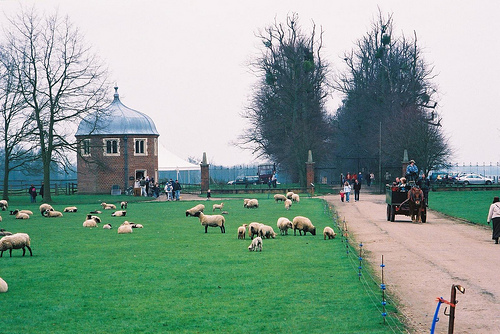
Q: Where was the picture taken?
A: It was taken at the field.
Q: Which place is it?
A: It is a field.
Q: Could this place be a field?
A: Yes, it is a field.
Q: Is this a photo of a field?
A: Yes, it is showing a field.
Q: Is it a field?
A: Yes, it is a field.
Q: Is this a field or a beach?
A: It is a field.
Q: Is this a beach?
A: No, it is a field.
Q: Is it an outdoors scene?
A: Yes, it is outdoors.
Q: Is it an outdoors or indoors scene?
A: It is outdoors.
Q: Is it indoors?
A: No, it is outdoors.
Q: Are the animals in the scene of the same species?
A: Yes, all the animals are sheep.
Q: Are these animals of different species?
A: No, all the animals are sheep.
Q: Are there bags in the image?
A: No, there are no bags.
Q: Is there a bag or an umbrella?
A: No, there are no bags or umbrellas.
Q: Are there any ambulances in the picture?
A: No, there are no ambulances.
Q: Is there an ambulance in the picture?
A: No, there are no ambulances.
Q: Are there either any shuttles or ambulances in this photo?
A: No, there are no ambulances or shuttles.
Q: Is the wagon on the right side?
A: Yes, the wagon is on the right of the image.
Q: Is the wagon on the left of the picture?
A: No, the wagon is on the right of the image.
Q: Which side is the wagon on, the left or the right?
A: The wagon is on the right of the image.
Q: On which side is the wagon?
A: The wagon is on the right of the image.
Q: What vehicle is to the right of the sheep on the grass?
A: The vehicle is a wagon.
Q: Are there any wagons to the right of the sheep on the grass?
A: Yes, there is a wagon to the right of the sheep.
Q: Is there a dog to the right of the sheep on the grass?
A: No, there is a wagon to the right of the sheep.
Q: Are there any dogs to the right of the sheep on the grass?
A: No, there is a wagon to the right of the sheep.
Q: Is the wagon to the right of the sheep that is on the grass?
A: Yes, the wagon is to the right of the sheep.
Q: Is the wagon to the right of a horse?
A: No, the wagon is to the right of the sheep.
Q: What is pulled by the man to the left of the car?
A: The wagon is pulled by the man.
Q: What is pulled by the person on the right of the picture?
A: The wagon is pulled by the man.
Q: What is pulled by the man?
A: The wagon is pulled by the man.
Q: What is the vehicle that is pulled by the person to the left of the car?
A: The vehicle is a wagon.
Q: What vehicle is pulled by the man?
A: The vehicle is a wagon.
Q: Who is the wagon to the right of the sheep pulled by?
A: The wagon is pulled by the man.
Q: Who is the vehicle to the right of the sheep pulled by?
A: The wagon is pulled by the man.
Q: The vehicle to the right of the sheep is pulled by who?
A: The wagon is pulled by the man.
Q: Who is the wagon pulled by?
A: The wagon is pulled by the man.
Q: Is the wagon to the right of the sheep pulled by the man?
A: Yes, the wagon is pulled by the man.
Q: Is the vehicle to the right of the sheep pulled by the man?
A: Yes, the wagon is pulled by the man.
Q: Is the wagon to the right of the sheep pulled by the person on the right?
A: Yes, the wagon is pulled by the man.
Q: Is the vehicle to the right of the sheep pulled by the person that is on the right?
A: Yes, the wagon is pulled by the man.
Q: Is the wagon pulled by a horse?
A: No, the wagon is pulled by the man.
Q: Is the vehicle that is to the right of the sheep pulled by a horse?
A: No, the wagon is pulled by the man.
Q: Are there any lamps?
A: No, there are no lamps.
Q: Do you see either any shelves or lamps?
A: No, there are no lamps or shelves.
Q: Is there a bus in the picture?
A: No, there are no buses.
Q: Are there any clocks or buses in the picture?
A: No, there are no buses or clocks.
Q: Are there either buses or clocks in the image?
A: No, there are no buses or clocks.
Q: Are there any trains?
A: No, there are no trains.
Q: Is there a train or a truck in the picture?
A: No, there are no trains or trucks.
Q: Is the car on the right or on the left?
A: The car is on the right of the image.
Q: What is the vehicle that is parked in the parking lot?
A: The vehicle is a car.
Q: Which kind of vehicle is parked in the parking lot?
A: The vehicle is a car.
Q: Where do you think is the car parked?
A: The car is parked in the parking lot.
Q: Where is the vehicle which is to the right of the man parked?
A: The car is parked in the parking lot.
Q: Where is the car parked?
A: The car is parked in the parking lot.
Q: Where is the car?
A: The car is on the road.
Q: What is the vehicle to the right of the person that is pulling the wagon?
A: The vehicle is a car.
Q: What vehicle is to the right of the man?
A: The vehicle is a car.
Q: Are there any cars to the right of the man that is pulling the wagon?
A: Yes, there is a car to the right of the man.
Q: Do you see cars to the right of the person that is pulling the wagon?
A: Yes, there is a car to the right of the man.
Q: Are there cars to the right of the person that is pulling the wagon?
A: Yes, there is a car to the right of the man.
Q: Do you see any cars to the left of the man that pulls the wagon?
A: No, the car is to the right of the man.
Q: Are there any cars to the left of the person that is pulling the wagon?
A: No, the car is to the right of the man.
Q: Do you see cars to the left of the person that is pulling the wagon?
A: No, the car is to the right of the man.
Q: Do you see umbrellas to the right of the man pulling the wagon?
A: No, there is a car to the right of the man.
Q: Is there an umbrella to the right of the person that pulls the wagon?
A: No, there is a car to the right of the man.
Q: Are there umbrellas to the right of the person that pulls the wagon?
A: No, there is a car to the right of the man.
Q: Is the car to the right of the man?
A: Yes, the car is to the right of the man.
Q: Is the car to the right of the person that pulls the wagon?
A: Yes, the car is to the right of the man.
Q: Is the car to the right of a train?
A: No, the car is to the right of the man.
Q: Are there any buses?
A: No, there are no buses.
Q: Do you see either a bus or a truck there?
A: No, there are no buses or trucks.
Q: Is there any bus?
A: No, there are no buses.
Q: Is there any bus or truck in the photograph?
A: No, there are no buses or trucks.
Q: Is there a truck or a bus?
A: No, there are no buses or trucks.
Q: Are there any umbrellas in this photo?
A: No, there are no umbrellas.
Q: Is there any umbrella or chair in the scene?
A: No, there are no umbrellas or chairs.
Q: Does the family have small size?
A: Yes, the family is small.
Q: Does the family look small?
A: Yes, the family is small.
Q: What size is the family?
A: The family is small.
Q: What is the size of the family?
A: The family is small.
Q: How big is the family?
A: The family is small.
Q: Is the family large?
A: No, the family is small.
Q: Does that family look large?
A: No, the family is small.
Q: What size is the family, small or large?
A: The family is small.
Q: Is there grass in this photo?
A: Yes, there is grass.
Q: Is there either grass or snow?
A: Yes, there is grass.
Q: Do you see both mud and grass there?
A: No, there is grass but no mud.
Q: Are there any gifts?
A: No, there are no gifts.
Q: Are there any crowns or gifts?
A: No, there are no gifts or crowns.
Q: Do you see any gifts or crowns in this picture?
A: No, there are no gifts or crowns.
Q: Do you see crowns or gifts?
A: No, there are no gifts or crowns.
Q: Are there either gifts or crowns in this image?
A: No, there are no gifts or crowns.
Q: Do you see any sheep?
A: Yes, there is a sheep.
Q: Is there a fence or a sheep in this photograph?
A: Yes, there is a sheep.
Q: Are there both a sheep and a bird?
A: No, there is a sheep but no birds.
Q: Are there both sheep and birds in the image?
A: No, there is a sheep but no birds.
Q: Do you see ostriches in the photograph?
A: No, there are no ostriches.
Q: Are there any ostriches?
A: No, there are no ostriches.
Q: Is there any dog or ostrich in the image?
A: No, there are no ostriches or dogs.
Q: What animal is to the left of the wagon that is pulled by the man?
A: The animal is a sheep.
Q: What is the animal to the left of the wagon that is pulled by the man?
A: The animal is a sheep.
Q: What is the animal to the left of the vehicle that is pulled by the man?
A: The animal is a sheep.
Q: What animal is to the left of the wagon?
A: The animal is a sheep.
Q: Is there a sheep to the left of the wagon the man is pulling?
A: Yes, there is a sheep to the left of the wagon.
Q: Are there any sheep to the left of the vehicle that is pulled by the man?
A: Yes, there is a sheep to the left of the wagon.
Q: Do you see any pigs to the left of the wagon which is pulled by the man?
A: No, there is a sheep to the left of the wagon.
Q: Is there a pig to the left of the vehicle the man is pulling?
A: No, there is a sheep to the left of the wagon.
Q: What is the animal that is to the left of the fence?
A: The animal is a sheep.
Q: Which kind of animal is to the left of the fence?
A: The animal is a sheep.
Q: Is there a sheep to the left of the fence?
A: Yes, there is a sheep to the left of the fence.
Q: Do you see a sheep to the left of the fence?
A: Yes, there is a sheep to the left of the fence.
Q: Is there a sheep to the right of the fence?
A: No, the sheep is to the left of the fence.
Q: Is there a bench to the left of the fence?
A: No, there is a sheep to the left of the fence.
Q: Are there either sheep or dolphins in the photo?
A: Yes, there is a sheep.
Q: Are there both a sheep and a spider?
A: No, there is a sheep but no spiders.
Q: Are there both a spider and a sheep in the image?
A: No, there is a sheep but no spiders.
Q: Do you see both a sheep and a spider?
A: No, there is a sheep but no spiders.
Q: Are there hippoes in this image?
A: No, there are no hippoes.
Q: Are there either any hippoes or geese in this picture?
A: No, there are no hippoes or geese.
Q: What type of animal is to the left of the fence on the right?
A: The animal is a sheep.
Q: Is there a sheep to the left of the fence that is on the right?
A: Yes, there is a sheep to the left of the fence.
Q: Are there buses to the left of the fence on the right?
A: No, there is a sheep to the left of the fence.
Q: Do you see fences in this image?
A: Yes, there is a fence.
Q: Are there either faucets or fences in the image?
A: Yes, there is a fence.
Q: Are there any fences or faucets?
A: Yes, there is a fence.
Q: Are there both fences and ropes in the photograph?
A: No, there is a fence but no ropes.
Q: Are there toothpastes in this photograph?
A: No, there are no toothpastes.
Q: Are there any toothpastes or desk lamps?
A: No, there are no toothpastes or desk lamps.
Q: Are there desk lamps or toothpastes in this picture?
A: No, there are no toothpastes or desk lamps.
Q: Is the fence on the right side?
A: Yes, the fence is on the right of the image.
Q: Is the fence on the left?
A: No, the fence is on the right of the image.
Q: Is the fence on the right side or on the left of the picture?
A: The fence is on the right of the image.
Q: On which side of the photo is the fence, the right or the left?
A: The fence is on the right of the image.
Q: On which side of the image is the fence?
A: The fence is on the right of the image.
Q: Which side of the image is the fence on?
A: The fence is on the right of the image.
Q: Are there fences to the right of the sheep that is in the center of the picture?
A: Yes, there is a fence to the right of the sheep.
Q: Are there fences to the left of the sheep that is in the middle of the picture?
A: No, the fence is to the right of the sheep.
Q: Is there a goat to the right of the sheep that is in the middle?
A: No, there is a fence to the right of the sheep.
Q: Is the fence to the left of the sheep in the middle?
A: No, the fence is to the right of the sheep.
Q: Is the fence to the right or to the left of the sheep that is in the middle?
A: The fence is to the right of the sheep.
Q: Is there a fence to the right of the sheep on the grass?
A: Yes, there is a fence to the right of the sheep.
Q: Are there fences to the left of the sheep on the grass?
A: No, the fence is to the right of the sheep.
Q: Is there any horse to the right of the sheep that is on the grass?
A: No, there is a fence to the right of the sheep.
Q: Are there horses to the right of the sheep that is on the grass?
A: No, there is a fence to the right of the sheep.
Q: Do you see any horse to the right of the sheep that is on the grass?
A: No, there is a fence to the right of the sheep.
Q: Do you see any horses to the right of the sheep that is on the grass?
A: No, there is a fence to the right of the sheep.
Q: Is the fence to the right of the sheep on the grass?
A: Yes, the fence is to the right of the sheep.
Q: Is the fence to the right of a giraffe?
A: No, the fence is to the right of the sheep.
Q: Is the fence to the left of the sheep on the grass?
A: No, the fence is to the right of the sheep.